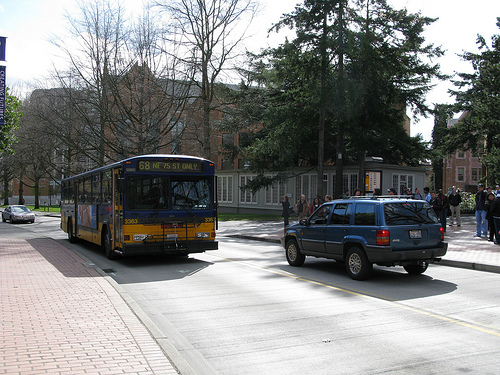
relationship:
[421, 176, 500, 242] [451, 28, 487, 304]
people on side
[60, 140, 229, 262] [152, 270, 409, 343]
bus on road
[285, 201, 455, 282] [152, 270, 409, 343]
car on road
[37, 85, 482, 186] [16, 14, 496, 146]
buildings in background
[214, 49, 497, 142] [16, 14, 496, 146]
trees in background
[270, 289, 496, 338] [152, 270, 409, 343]
markings in road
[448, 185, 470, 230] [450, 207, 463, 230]
guy in trousers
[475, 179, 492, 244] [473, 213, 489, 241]
guy in jeans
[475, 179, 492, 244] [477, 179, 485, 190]
guy wearing cap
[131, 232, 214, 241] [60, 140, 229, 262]
headlights on bus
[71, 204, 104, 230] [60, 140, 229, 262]
sign on bus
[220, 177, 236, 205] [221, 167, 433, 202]
windows on building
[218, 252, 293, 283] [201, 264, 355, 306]
shadow on ground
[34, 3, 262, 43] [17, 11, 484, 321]
sunny in picture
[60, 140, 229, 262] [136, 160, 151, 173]
bus has number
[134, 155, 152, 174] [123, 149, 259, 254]
65 in front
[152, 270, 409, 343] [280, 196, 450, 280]
road has car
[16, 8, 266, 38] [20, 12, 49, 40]
sky has clouds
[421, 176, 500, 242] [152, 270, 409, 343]
people by road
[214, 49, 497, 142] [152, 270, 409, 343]
trees on road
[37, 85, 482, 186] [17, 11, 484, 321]
buildings in picture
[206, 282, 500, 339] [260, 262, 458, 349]
street has lanes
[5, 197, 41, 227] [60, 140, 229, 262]
car behind bus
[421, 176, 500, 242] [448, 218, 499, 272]
people on sidewalk